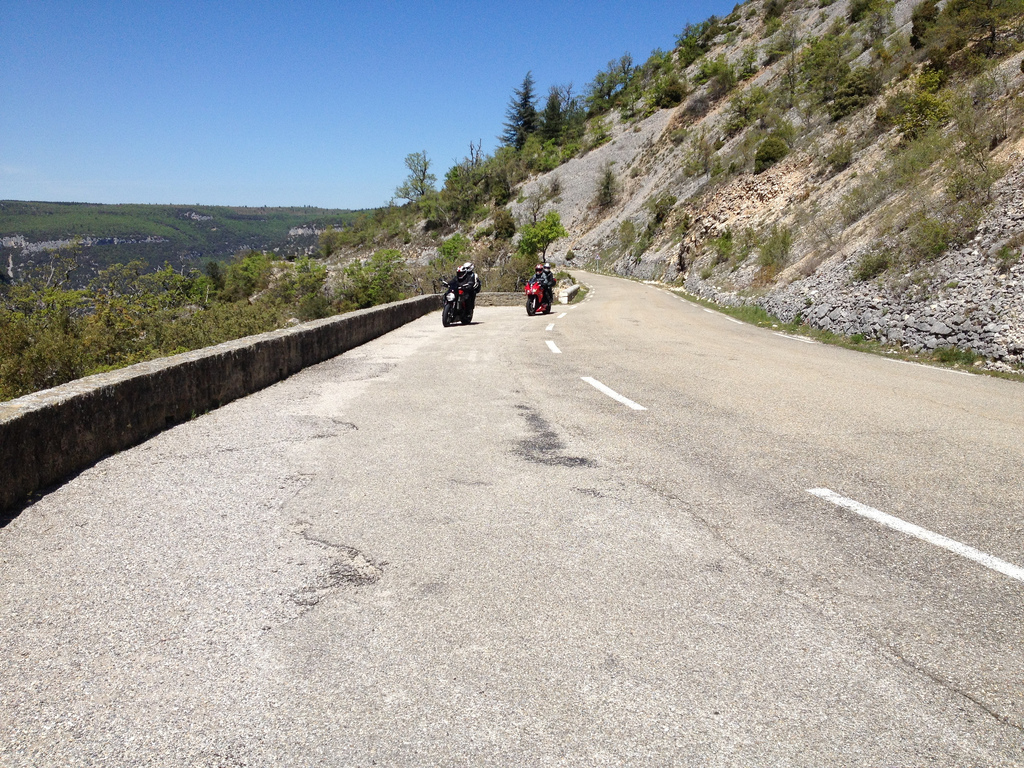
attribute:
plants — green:
[7, 234, 420, 387]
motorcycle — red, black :
[523, 278, 553, 313]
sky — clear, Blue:
[117, 30, 336, 242]